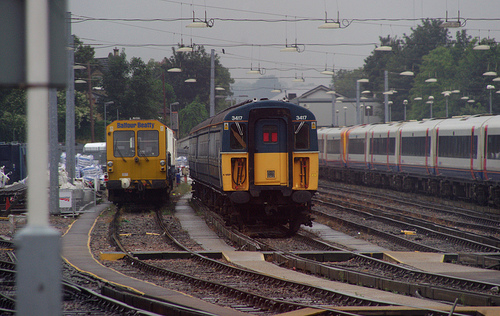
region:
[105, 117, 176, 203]
a yellow bus with blue trim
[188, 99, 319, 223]
a blue train with yellow trim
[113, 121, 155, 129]
blue writing on a yellow train car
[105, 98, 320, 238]
two yellow and blue trains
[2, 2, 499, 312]
a train station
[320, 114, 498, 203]
a row of white train cars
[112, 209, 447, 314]
a section of curved train track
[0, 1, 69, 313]
a sign hanging on a white pole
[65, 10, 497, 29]
a string of lights on a power line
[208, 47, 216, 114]
a grey metal pole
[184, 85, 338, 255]
A train on the tracks.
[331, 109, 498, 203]
A white train on tracks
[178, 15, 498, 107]
lights hanging from cables.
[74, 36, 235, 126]
Full green trees behind trains.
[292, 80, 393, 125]
White house behind the white train.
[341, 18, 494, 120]
Trees beside the white house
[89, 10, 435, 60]
overcast hazy looking sky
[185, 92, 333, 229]
This train is yellow and blue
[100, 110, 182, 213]
This train is yellow with windshield wipers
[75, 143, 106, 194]
white bags by the train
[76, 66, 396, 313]
yellow train on trail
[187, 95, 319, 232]
A train coming near the cameraman.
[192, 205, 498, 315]
The rail road of a yellow train.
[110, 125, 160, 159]
The two windows of a train.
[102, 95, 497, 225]
Three different trains riding at the same time.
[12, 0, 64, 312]
A white electric pole near the railroad.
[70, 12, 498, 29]
Electrical wires above the trains.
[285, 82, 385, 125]
An giant house in the distance.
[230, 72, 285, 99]
A grey tree very far in the horizon.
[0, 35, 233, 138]
A bunch of trees near the horizon.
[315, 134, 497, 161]
The windows of a very long train.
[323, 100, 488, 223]
A white train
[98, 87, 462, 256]
three trains on tracks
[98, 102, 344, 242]
two trains on tracks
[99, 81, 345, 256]
two yellow trains on tracks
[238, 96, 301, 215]
The door on a train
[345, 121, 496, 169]
The windows on a train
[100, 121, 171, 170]
The windshield on a train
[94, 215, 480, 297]
A bunch of train tracks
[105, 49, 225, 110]
green trees in the back ground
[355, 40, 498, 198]
green trees behind a white train